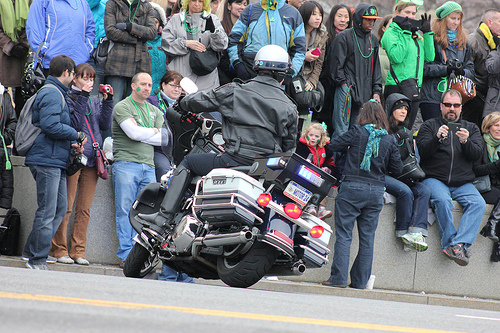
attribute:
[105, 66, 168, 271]
man — standing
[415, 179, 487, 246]
jeans — blue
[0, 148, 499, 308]
wall — cement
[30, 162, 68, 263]
jeans — blue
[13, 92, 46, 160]
backpack — grey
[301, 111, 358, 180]
child — small, blonde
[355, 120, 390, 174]
scarf — blue, knit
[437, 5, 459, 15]
hat — green, knit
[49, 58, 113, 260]
woman — standing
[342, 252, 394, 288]
cup — styrofoam, white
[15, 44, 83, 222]
man — dark haired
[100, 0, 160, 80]
coat — plaid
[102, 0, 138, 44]
arm — crossed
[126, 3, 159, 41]
arm — crossed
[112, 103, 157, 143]
arm — crossed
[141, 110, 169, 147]
arm — crossed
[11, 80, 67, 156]
backpack — gray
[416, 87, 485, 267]
man — sitting